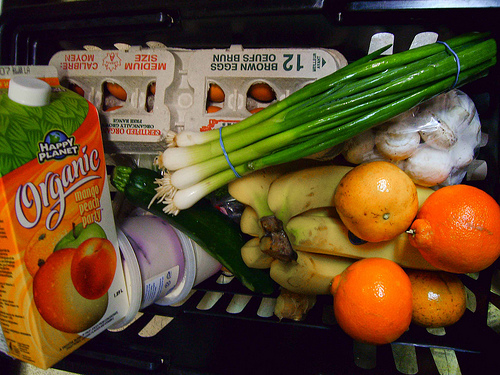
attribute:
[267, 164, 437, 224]
banana — yellow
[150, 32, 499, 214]
onions — green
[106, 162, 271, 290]
zucchini — green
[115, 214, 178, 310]
container — yogurt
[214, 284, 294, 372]
container — black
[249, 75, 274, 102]
egg — brown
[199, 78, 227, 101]
egg — brown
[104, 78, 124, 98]
egg — brown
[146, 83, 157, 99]
egg — brown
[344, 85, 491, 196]
mushrooms — plastic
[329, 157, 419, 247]
orange — bright, shiny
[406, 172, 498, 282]
orange — bright, shiny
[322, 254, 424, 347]
orange — bright, shiny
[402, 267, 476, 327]
orange — bright, shiny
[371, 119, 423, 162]
vegetable — fresh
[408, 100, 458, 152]
vegetable — fresh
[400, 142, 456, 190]
vegetable — fresh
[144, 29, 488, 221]
vegetable — fresh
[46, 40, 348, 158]
eggs — brown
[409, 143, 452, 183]
mushroom — delicious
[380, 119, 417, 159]
mushroom — delicious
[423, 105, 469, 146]
mushroom — delicious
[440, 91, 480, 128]
mushroom — delicious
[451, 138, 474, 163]
mushroom — delicious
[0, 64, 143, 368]
container — yogurt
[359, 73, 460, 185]
mushrooms — white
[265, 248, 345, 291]
banana — yellow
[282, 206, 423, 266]
banana — yellow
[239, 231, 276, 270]
banana — yellow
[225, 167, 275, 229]
banana — yellow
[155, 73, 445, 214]
onions — green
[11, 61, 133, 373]
carton — juice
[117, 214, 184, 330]
tub — yogurt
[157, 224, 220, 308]
tub — yogurt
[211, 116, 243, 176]
rubber band — blue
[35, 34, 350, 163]
eggs — brown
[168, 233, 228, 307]
yogurt container — on side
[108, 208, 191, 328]
yogurt container — on side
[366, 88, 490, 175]
bag — white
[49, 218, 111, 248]
apple — green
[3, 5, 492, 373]
basket — black, plastic